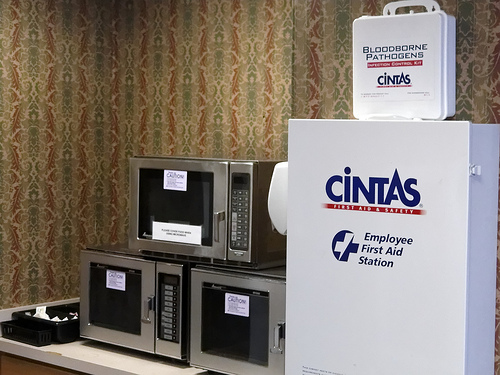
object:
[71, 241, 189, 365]
microwave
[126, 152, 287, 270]
microwave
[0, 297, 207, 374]
counter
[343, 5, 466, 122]
kit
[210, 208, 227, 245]
handle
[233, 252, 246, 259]
button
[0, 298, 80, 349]
basket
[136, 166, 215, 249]
door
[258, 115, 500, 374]
case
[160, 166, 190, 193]
label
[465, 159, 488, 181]
station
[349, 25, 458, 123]
first aid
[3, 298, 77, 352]
tray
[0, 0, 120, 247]
wallpaper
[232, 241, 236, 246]
number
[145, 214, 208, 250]
sticker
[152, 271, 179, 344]
food selector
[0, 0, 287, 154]
curtain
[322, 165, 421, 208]
letter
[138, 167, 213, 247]
glass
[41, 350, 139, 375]
top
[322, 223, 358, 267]
symbol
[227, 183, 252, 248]
switch